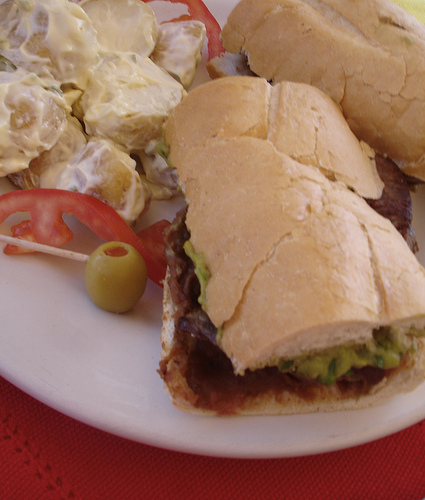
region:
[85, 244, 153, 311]
Green olive on plate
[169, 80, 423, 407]
Sandwich lying on a plate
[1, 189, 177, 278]
Piece of tomato on a plate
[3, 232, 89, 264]
Toothpick in front of tomato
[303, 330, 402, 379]
Broccoli inside sandwich on plate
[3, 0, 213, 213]
Potato salad on a plate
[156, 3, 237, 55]
Tomato behind potato salad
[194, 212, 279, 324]
Crusty flaked bread on sandwich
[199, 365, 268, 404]
Sauce inside sandwich bread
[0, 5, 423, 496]
a sandwich meal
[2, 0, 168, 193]
potato salad right of plate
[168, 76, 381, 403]
meat filled sandwich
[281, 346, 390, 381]
avocado in sandwich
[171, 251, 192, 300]
beans in the sandwich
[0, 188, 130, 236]
slice of tomato right of sandwich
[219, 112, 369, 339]
sandwich bread slices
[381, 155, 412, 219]
piece of steak meat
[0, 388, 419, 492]
The tablecloth is red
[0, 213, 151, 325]
Olive with a toothpick in it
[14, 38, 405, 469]
The plate is white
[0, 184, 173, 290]
Slice of tomato on the plate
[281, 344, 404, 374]
Guacamole on the sandwich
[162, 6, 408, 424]
The sandwich is on a sub roll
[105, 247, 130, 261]
Pimento in the olive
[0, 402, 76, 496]
Stitches on the tablecloth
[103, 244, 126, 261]
a filling is on the olive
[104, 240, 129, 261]
the filling is red in color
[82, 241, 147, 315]
the olive is green in color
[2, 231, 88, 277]
a stick is on the olive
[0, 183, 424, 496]
the dish is white in color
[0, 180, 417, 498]
the dish is ceramic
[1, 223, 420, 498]
the dish is shiny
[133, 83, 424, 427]
a sandwich is on the dish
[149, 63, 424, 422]
the sanwich has bread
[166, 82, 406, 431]
a large half of a sandwhich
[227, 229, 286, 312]
a cracked piece of bread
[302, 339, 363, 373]
a piece of green vegetable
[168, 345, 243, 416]
some sauce on some bread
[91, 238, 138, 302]
a green pimento olive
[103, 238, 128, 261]
the red pimento of an olive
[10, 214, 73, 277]
a skinny little wooden toothpick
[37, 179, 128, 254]
a small piece of red tomato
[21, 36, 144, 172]
a bunch of potato salad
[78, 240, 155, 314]
small green olive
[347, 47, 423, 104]
food on a plate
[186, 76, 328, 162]
food on a plate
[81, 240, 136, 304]
olive on a plate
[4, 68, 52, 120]
food on a plate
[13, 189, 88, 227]
tomatoe on a plate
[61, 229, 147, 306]
green olive on the plate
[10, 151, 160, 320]
a tomato on the plate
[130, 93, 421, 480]
a sandwich on th eplate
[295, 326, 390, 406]
lettuce on the sandwich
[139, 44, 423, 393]
sandwich cut in half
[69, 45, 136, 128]
potatos covered in sauce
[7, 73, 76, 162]
potatos covered in sauce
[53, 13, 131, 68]
potatos coverd in sauce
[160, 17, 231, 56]
tomato on th eplate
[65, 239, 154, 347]
Olive on a plate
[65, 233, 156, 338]
Olive on a plate